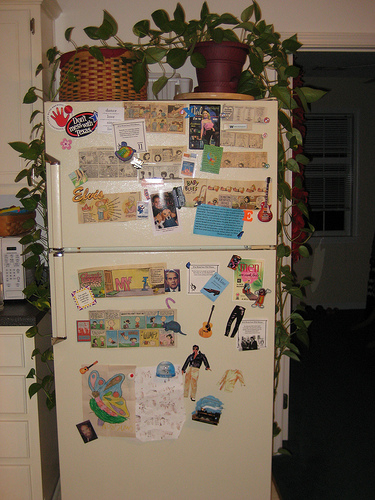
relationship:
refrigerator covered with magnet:
[39, 96, 283, 500] [59, 135, 74, 153]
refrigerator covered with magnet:
[39, 96, 283, 500] [240, 207, 256, 224]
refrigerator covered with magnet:
[39, 96, 283, 500] [256, 175, 276, 224]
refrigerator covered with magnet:
[39, 96, 283, 500] [198, 303, 217, 341]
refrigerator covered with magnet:
[39, 96, 283, 500] [223, 304, 247, 340]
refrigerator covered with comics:
[39, 96, 283, 500] [77, 259, 171, 302]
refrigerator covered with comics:
[39, 96, 283, 500] [89, 307, 180, 352]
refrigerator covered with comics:
[39, 96, 283, 500] [75, 187, 145, 227]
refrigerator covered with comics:
[39, 96, 283, 500] [213, 130, 267, 152]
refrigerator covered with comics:
[39, 96, 283, 500] [178, 175, 275, 212]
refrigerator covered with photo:
[39, 96, 283, 500] [147, 190, 182, 232]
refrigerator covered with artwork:
[39, 96, 283, 500] [81, 364, 140, 442]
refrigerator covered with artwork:
[39, 96, 283, 500] [134, 362, 193, 444]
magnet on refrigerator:
[59, 135, 74, 153] [39, 96, 283, 500]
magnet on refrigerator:
[240, 207, 256, 224] [39, 96, 283, 500]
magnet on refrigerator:
[256, 175, 276, 224] [39, 96, 283, 500]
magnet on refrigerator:
[198, 303, 217, 341] [39, 96, 283, 500]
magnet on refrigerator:
[223, 304, 247, 340] [39, 96, 283, 500]